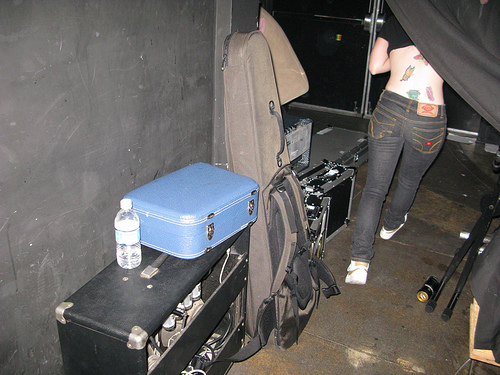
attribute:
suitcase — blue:
[120, 129, 272, 260]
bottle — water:
[109, 186, 144, 271]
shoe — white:
[344, 258, 368, 287]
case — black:
[54, 221, 251, 373]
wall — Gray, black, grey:
[0, 0, 215, 374]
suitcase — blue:
[124, 160, 258, 257]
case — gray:
[261, 136, 388, 257]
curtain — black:
[384, 0, 499, 132]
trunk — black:
[287, 159, 359, 246]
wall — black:
[8, 9, 148, 170]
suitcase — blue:
[95, 90, 284, 298]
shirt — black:
[373, 23, 418, 52]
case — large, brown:
[77, 127, 336, 323]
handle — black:
[261, 93, 292, 177]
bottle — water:
[88, 196, 155, 272]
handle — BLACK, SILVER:
[141, 252, 170, 278]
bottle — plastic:
[113, 197, 144, 270]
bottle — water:
[111, 196, 143, 271]